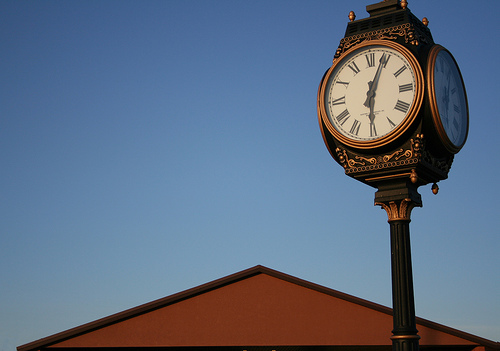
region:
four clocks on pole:
[309, 13, 478, 250]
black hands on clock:
[359, 45, 389, 134]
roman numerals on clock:
[326, 58, 366, 130]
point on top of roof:
[199, 252, 347, 292]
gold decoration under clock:
[346, 150, 422, 171]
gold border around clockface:
[391, 37, 416, 56]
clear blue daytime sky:
[89, 29, 265, 167]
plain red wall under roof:
[214, 294, 288, 336]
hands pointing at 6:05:
[351, 49, 389, 133]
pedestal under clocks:
[366, 178, 429, 214]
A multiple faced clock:
[312, 28, 475, 205]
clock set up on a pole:
[260, 50, 444, 338]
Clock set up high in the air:
[7, 3, 474, 341]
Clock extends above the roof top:
[13, 216, 499, 348]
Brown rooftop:
[121, 266, 418, 345]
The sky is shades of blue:
[11, 109, 405, 296]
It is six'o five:
[326, 16, 422, 163]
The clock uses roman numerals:
[325, 91, 357, 111]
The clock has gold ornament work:
[343, 136, 432, 224]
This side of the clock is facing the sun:
[286, 29, 472, 217]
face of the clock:
[314, 44, 424, 142]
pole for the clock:
[377, 190, 416, 350]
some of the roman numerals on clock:
[393, 66, 409, 111]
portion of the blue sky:
[58, 30, 258, 197]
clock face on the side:
[427, 50, 472, 155]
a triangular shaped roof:
[51, 270, 369, 345]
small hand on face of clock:
[368, 101, 379, 128]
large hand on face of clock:
[364, 56, 394, 102]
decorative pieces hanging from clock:
[407, 167, 449, 194]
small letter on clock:
[360, 109, 382, 115]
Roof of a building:
[3, 250, 498, 350]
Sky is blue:
[4, 8, 316, 257]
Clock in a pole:
[307, 7, 484, 342]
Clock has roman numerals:
[309, 34, 426, 154]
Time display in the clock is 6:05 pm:
[305, 30, 431, 155]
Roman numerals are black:
[310, 30, 427, 150]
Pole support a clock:
[365, 180, 437, 346]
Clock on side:
[423, 36, 478, 153]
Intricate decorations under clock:
[326, 138, 432, 178]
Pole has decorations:
[374, 196, 428, 350]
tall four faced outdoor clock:
[306, 0, 466, 186]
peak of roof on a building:
[15, 261, 496, 341]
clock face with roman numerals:
[317, 46, 421, 144]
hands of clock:
[367, 50, 385, 129]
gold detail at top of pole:
[371, 195, 422, 226]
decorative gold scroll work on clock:
[327, 136, 430, 176]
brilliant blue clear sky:
[5, 4, 499, 331]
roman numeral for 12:
[364, 46, 381, 69]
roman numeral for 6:
[367, 116, 379, 139]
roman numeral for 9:
[330, 98, 343, 111]